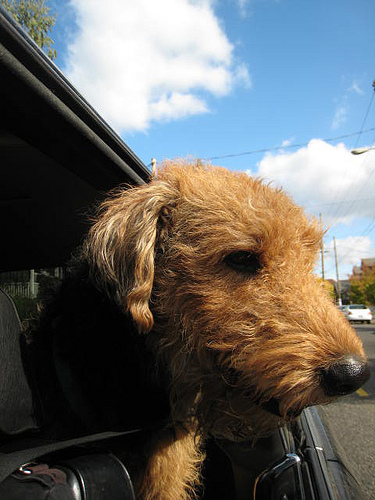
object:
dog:
[20, 155, 369, 500]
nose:
[320, 355, 371, 398]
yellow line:
[356, 387, 369, 398]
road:
[315, 323, 375, 497]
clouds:
[319, 236, 374, 265]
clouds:
[331, 74, 362, 130]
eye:
[223, 249, 263, 276]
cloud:
[246, 138, 375, 224]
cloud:
[61, 1, 251, 138]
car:
[339, 304, 372, 324]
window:
[0, 44, 330, 499]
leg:
[137, 380, 206, 500]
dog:
[57, 166, 350, 498]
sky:
[8, 1, 371, 281]